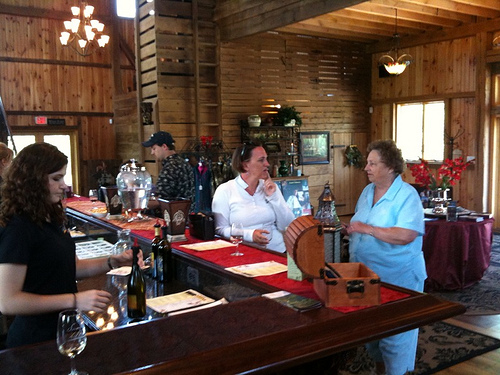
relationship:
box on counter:
[284, 217, 387, 317] [71, 188, 450, 371]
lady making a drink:
[0, 141, 116, 359] [89, 267, 133, 322]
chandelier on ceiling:
[57, 5, 119, 55] [22, 8, 484, 37]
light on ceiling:
[379, 18, 411, 78] [16, 6, 480, 44]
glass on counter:
[54, 305, 93, 370] [44, 178, 479, 371]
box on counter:
[284, 217, 387, 317] [44, 178, 479, 371]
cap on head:
[139, 132, 179, 148] [146, 125, 179, 160]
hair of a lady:
[13, 133, 65, 212] [5, 138, 115, 360]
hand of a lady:
[76, 281, 110, 312] [5, 138, 115, 360]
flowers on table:
[410, 143, 472, 199] [424, 221, 484, 289]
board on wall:
[139, 84, 160, 105] [3, 30, 363, 191]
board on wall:
[137, 66, 159, 82] [3, 30, 363, 191]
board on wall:
[140, 56, 160, 72] [5, 42, 362, 197]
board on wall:
[137, 25, 158, 42] [10, 43, 362, 225]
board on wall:
[135, 4, 163, 107] [9, 4, 205, 172]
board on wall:
[134, 0, 161, 22] [5, 8, 225, 182]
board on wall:
[285, 218, 317, 273] [287, 211, 327, 272]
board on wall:
[298, 212, 323, 234] [280, 218, 325, 288]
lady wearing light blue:
[344, 141, 427, 364] [345, 177, 432, 371]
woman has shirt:
[206, 132, 297, 278] [214, 175, 297, 249]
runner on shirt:
[64, 180, 424, 332] [351, 174, 428, 288]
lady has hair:
[0, 141, 116, 359] [1, 134, 69, 241]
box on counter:
[284, 217, 387, 317] [7, 185, 472, 373]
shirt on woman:
[351, 174, 436, 287] [342, 135, 442, 374]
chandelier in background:
[57, 5, 119, 55] [6, 4, 141, 222]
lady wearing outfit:
[344, 141, 427, 364] [350, 177, 428, 370]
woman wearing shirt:
[211, 142, 298, 254] [208, 171, 293, 254]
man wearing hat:
[147, 122, 205, 222] [140, 129, 183, 150]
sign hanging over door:
[26, 112, 57, 132] [4, 133, 84, 197]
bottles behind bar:
[135, 218, 189, 304] [11, 179, 472, 372]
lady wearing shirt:
[0, 141, 116, 359] [3, 203, 89, 342]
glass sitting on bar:
[54, 305, 93, 370] [11, 179, 472, 372]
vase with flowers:
[409, 150, 471, 225] [398, 150, 468, 200]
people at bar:
[131, 118, 431, 278] [30, 235, 349, 367]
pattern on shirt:
[179, 161, 190, 173] [151, 153, 203, 210]